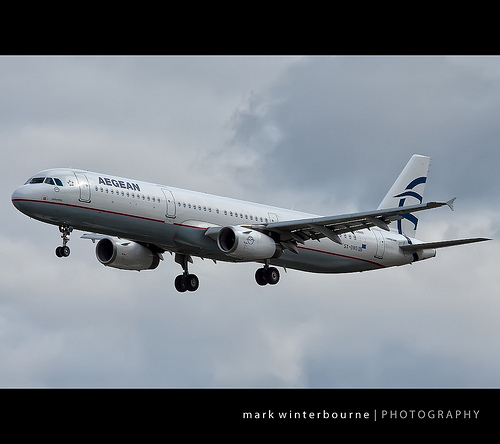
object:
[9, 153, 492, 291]
plane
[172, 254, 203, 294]
landing gear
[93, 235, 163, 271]
engine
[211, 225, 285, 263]
engine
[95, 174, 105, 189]
letters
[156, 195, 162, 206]
windows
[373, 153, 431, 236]
tail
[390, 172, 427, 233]
symbol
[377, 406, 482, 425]
words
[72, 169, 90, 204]
door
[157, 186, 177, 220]
door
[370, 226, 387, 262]
door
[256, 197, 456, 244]
wings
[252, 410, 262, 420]
letter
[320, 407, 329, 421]
letter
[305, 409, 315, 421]
letter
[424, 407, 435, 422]
letter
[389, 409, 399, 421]
letter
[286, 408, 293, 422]
letter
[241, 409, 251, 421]
letter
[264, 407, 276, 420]
letter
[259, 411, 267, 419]
letter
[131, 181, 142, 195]
letter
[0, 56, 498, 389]
sky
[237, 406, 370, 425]
photographer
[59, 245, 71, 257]
wheels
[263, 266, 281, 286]
wheels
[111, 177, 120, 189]
letter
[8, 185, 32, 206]
nose